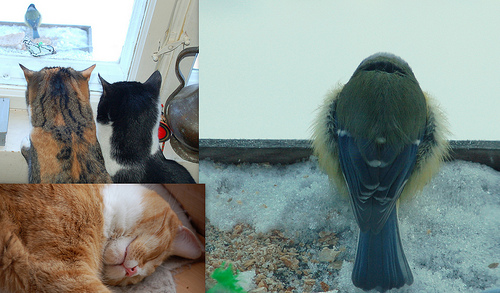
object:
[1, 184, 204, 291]
cat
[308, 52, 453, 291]
bird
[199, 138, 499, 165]
gutter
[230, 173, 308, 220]
snow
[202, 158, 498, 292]
roof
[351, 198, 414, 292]
tail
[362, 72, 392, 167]
feathers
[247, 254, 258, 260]
seeds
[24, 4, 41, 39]
bird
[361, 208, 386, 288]
feather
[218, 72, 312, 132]
snow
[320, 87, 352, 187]
wings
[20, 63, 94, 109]
head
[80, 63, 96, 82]
ear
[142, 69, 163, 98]
ear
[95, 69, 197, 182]
cat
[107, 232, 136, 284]
mouth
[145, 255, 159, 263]
eye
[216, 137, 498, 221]
ground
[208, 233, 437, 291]
ground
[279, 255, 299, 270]
rocks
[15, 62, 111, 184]
cat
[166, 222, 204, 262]
ear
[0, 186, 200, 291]
kitty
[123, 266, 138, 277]
nose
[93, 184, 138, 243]
patch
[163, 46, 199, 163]
kettle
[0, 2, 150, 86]
window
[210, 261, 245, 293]
object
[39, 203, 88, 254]
kitten fur